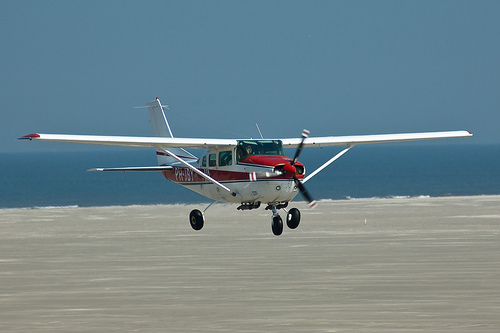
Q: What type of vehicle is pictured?
A: Airplane.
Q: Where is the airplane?
A: In the air.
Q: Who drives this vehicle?
A: Pilot.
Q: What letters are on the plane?
A: PH.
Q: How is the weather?
A: Sunny and clear.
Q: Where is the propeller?
A: Plane's nose.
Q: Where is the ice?
A: Beneath the plane.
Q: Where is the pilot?
A: In the cockpit.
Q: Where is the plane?
A: In the air.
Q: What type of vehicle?
A: Plane.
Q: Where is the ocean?
A: Behind the plane.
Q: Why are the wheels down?
A: The plane is landing.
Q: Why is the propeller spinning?
A: The plane is flying.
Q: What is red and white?
A: The plane.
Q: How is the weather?
A: Clear.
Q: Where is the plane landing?
A: On the beach.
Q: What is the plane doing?
A: Flying.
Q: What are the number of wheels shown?
A: Three.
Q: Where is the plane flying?
A: Over water.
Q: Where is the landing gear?
A: Under the plane.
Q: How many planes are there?
A: One.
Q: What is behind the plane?
A: The ocean.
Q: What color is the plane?
A: Red and white.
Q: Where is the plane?
A: The air.